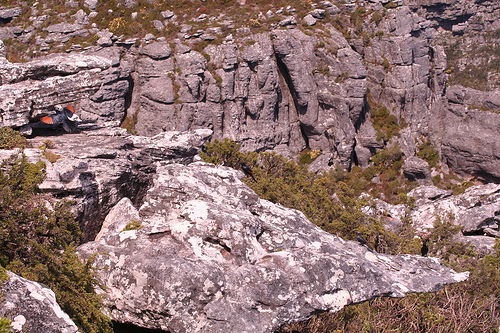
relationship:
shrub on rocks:
[4, 33, 103, 64] [6, 6, 496, 331]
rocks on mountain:
[6, 6, 496, 331] [38, 24, 403, 293]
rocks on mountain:
[6, 6, 496, 331] [1, 0, 500, 333]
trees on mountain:
[6, 164, 80, 287] [1, 0, 500, 333]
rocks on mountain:
[6, 6, 496, 331] [6, 12, 498, 323]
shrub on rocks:
[231, 3, 291, 30] [6, 6, 496, 331]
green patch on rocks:
[447, 46, 498, 85] [6, 6, 496, 331]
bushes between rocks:
[212, 109, 451, 261] [6, 6, 496, 331]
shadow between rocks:
[273, 50, 303, 119] [6, 6, 496, 331]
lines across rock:
[139, 91, 265, 107] [2, 45, 467, 129]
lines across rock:
[139, 82, 266, 107] [2, 45, 467, 129]